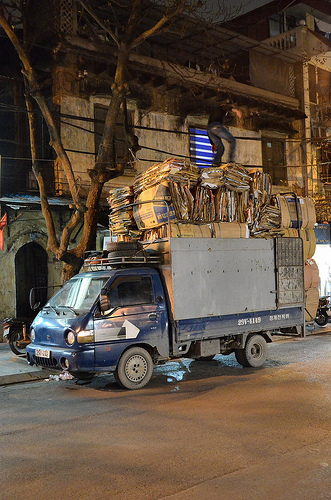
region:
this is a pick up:
[48, 147, 323, 385]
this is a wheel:
[116, 346, 155, 389]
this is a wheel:
[239, 327, 276, 371]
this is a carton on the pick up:
[132, 184, 172, 224]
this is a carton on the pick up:
[139, 154, 199, 179]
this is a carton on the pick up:
[123, 183, 202, 231]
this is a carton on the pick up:
[208, 207, 262, 241]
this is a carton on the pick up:
[219, 156, 258, 197]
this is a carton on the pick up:
[261, 184, 324, 231]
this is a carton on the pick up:
[295, 236, 320, 318]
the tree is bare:
[35, 0, 213, 140]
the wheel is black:
[102, 344, 164, 396]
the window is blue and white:
[180, 126, 231, 165]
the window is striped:
[173, 115, 227, 165]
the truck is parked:
[12, 181, 310, 367]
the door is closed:
[72, 261, 173, 374]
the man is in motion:
[195, 95, 252, 163]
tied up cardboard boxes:
[100, 142, 297, 228]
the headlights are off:
[7, 318, 77, 343]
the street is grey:
[89, 387, 314, 485]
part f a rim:
[132, 363, 143, 377]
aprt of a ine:
[236, 455, 253, 473]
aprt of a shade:
[199, 412, 215, 436]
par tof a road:
[234, 453, 241, 464]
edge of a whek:
[113, 346, 139, 403]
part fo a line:
[217, 454, 232, 481]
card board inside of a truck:
[115, 137, 321, 318]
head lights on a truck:
[25, 323, 77, 344]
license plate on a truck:
[33, 345, 50, 361]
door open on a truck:
[273, 231, 306, 310]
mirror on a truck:
[99, 290, 113, 311]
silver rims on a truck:
[123, 352, 153, 388]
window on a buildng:
[186, 119, 218, 172]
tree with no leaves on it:
[24, 116, 97, 262]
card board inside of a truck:
[51, 154, 321, 403]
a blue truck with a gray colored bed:
[23, 238, 302, 388]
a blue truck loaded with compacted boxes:
[25, 155, 316, 388]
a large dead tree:
[0, 3, 263, 285]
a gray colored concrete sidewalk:
[1, 308, 329, 382]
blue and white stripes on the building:
[185, 123, 215, 167]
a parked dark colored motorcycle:
[3, 314, 33, 358]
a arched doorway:
[13, 240, 47, 322]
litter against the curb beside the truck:
[40, 372, 72, 382]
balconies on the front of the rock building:
[31, 3, 327, 98]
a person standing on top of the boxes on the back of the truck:
[22, 99, 320, 387]